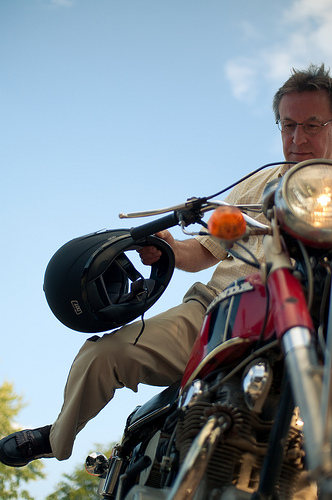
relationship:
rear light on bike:
[86, 455, 110, 479] [85, 158, 332, 499]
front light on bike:
[272, 156, 330, 249] [85, 158, 332, 499]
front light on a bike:
[272, 156, 330, 249] [85, 158, 332, 499]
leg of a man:
[46, 303, 209, 457] [50, 68, 332, 459]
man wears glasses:
[50, 68, 332, 459] [280, 114, 332, 137]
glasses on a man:
[280, 114, 332, 137] [50, 68, 332, 459]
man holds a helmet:
[50, 68, 332, 459] [43, 223, 176, 334]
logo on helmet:
[67, 297, 87, 320] [43, 223, 176, 334]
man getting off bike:
[50, 68, 332, 459] [85, 158, 332, 499]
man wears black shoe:
[50, 68, 332, 459] [1, 427, 60, 465]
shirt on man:
[197, 163, 306, 290] [50, 68, 332, 459]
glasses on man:
[280, 114, 332, 137] [50, 68, 332, 459]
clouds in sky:
[223, 4, 331, 109] [4, 1, 331, 500]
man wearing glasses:
[50, 68, 332, 459] [280, 114, 332, 137]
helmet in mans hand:
[43, 223, 176, 334] [134, 226, 175, 266]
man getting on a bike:
[50, 68, 332, 459] [85, 158, 332, 499]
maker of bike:
[199, 281, 261, 315] [85, 158, 332, 499]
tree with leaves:
[1, 388, 48, 499] [1, 378, 123, 500]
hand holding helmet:
[134, 226, 175, 266] [43, 223, 176, 334]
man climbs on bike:
[50, 68, 332, 459] [85, 158, 332, 499]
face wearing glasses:
[275, 90, 331, 162] [280, 114, 332, 137]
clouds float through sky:
[223, 4, 331, 109] [4, 1, 331, 500]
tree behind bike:
[1, 388, 48, 499] [85, 158, 332, 499]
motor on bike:
[111, 362, 299, 500] [85, 158, 332, 499]